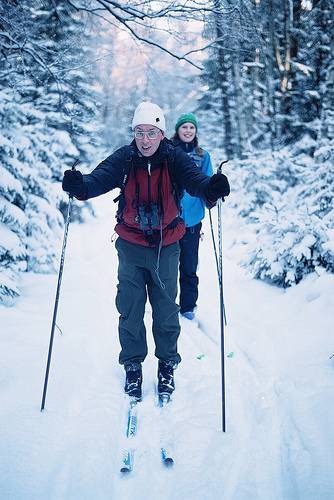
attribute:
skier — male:
[61, 101, 231, 398]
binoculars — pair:
[120, 196, 158, 234]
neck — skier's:
[134, 145, 168, 160]